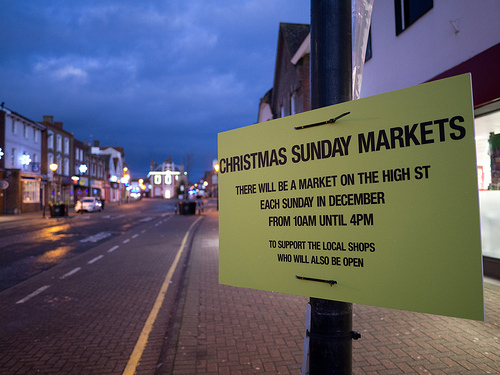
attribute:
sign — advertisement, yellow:
[214, 69, 485, 319]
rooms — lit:
[152, 175, 174, 184]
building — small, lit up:
[142, 155, 193, 204]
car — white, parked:
[72, 194, 104, 217]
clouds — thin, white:
[25, 2, 260, 121]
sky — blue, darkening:
[1, 0, 309, 184]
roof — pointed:
[277, 20, 313, 57]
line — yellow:
[121, 213, 206, 374]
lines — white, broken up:
[13, 206, 178, 308]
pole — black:
[306, 1, 349, 374]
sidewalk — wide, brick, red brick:
[170, 199, 499, 374]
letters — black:
[216, 112, 469, 270]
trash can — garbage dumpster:
[176, 197, 200, 218]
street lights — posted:
[45, 158, 59, 213]